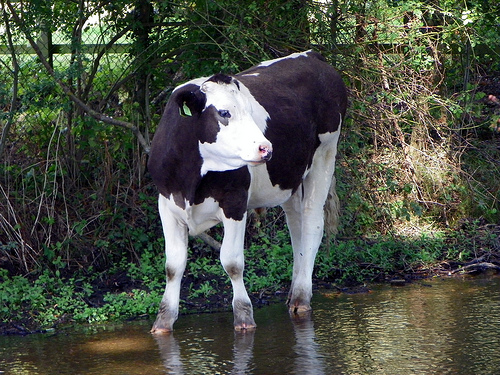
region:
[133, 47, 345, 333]
a black and white cow looking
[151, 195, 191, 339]
the white leg of a black and white cow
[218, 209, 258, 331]
the white leg of a black and white cow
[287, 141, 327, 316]
the white leg of a black and white cow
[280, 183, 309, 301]
the white leg of a black and white cow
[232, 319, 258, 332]
a brown hoof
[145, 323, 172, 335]
a brown hoof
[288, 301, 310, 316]
a brown hoof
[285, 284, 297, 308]
a brown hoof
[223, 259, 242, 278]
the black knee of a cow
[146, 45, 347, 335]
the cow standing in the water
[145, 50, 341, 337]
the cow is black and white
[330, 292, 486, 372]
the shallow brown water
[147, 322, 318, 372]
the cow's reflection in the water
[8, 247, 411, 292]
the short grass near the water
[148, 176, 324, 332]
the legs of the cow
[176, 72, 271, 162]
the head of the cow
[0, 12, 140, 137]
the metal wire fence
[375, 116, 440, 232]
the sun shining on the grass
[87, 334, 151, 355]
the sun shining on the water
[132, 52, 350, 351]
black and white cow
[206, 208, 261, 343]
leg of black and white cow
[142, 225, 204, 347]
leg of black and white cow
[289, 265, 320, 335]
leg of black and white cow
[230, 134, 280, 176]
nose of black and white cow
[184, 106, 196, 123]
green tag in ear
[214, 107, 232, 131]
eye of cow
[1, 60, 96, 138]
fence behind cow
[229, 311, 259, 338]
hoof of black and white cow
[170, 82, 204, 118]
ear of black and white cow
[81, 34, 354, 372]
a young cow waiting in a cow pond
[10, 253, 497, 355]
a muddy cow pond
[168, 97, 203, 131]
a green identification tag on a cow's ear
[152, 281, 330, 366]
a cow's hooves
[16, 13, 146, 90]
a wire fence with wood supports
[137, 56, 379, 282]
a spotted cow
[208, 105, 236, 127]
a cow's eye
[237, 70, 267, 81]
a white spot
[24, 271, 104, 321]
plants growing at the edge of the cow pond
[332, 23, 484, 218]
a thicket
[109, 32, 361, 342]
cow standing in the water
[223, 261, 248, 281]
dark spot on the leg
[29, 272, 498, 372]
shallow brown water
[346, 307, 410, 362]
small ripples in the water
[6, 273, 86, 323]
patch of green weeds growing in the dirt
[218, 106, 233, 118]
small black eye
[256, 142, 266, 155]
tiny pin nostril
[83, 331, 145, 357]
light shining on the water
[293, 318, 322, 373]
relfection of the cow's leg in the water